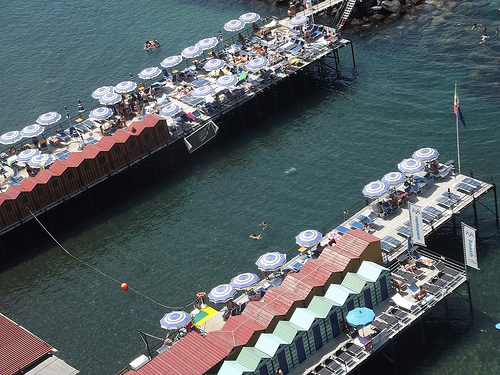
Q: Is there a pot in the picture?
A: No, there are no pots.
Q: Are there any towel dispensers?
A: No, there are no towel dispensers.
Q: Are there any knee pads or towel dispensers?
A: No, there are no towel dispensers or knee pads.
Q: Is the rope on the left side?
A: Yes, the rope is on the left of the image.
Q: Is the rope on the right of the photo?
A: No, the rope is on the left of the image.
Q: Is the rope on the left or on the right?
A: The rope is on the left of the image.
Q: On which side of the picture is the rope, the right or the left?
A: The rope is on the left of the image.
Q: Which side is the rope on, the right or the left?
A: The rope is on the left of the image.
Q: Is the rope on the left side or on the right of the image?
A: The rope is on the left of the image.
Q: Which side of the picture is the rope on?
A: The rope is on the left of the image.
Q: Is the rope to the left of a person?
A: Yes, the rope is to the left of a person.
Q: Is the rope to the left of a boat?
A: No, the rope is to the left of a person.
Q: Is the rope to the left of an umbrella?
A: Yes, the rope is to the left of an umbrella.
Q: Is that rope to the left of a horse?
A: No, the rope is to the left of an umbrella.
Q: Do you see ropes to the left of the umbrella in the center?
A: Yes, there is a rope to the left of the umbrella.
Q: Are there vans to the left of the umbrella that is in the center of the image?
A: No, there is a rope to the left of the umbrella.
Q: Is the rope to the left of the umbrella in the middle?
A: Yes, the rope is to the left of the umbrella.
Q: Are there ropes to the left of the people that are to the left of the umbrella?
A: Yes, there is a rope to the left of the people.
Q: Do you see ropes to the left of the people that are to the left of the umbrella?
A: Yes, there is a rope to the left of the people.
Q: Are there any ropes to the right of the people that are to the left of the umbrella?
A: No, the rope is to the left of the people.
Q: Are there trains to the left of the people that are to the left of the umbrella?
A: No, there is a rope to the left of the people.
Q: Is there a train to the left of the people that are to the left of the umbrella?
A: No, there is a rope to the left of the people.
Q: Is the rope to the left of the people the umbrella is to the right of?
A: Yes, the rope is to the left of the people.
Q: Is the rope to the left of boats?
A: No, the rope is to the left of the people.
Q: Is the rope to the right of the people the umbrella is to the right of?
A: No, the rope is to the left of the people.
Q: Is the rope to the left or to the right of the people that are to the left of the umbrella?
A: The rope is to the left of the people.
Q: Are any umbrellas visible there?
A: Yes, there is an umbrella.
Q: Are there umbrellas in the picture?
A: Yes, there is an umbrella.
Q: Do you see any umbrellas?
A: Yes, there is an umbrella.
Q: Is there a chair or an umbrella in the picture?
A: Yes, there is an umbrella.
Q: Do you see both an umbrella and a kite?
A: No, there is an umbrella but no kites.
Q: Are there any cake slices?
A: No, there are no cake slices.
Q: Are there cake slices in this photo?
A: No, there are no cake slices.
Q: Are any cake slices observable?
A: No, there are no cake slices.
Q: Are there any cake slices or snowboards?
A: No, there are no cake slices or snowboards.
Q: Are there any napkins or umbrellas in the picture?
A: Yes, there is an umbrella.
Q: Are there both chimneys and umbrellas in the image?
A: No, there is an umbrella but no chimneys.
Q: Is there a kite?
A: No, there are no kites.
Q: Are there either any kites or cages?
A: No, there are no kites or cages.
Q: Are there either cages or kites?
A: No, there are no kites or cages.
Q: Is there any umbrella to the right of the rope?
A: Yes, there is an umbrella to the right of the rope.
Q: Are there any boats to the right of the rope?
A: No, there is an umbrella to the right of the rope.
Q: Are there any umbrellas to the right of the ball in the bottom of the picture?
A: Yes, there is an umbrella to the right of the ball.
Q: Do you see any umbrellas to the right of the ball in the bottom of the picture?
A: Yes, there is an umbrella to the right of the ball.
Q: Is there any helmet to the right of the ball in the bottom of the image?
A: No, there is an umbrella to the right of the ball.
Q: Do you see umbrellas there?
A: Yes, there is an umbrella.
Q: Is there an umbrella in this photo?
A: Yes, there is an umbrella.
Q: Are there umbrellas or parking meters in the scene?
A: Yes, there is an umbrella.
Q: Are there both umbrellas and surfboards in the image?
A: No, there is an umbrella but no surfboards.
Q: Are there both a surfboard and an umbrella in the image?
A: No, there is an umbrella but no surfboards.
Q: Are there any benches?
A: No, there are no benches.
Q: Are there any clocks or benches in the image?
A: No, there are no benches or clocks.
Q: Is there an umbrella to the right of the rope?
A: Yes, there is an umbrella to the right of the rope.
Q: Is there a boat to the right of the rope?
A: No, there is an umbrella to the right of the rope.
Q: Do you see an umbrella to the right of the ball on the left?
A: Yes, there is an umbrella to the right of the ball.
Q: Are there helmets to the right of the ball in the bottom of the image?
A: No, there is an umbrella to the right of the ball.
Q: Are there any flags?
A: Yes, there is a flag.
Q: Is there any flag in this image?
A: Yes, there is a flag.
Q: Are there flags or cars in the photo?
A: Yes, there is a flag.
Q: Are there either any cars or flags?
A: Yes, there is a flag.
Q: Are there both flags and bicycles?
A: No, there is a flag but no bicycles.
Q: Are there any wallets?
A: No, there are no wallets.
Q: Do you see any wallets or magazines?
A: No, there are no wallets or magazines.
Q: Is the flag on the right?
A: Yes, the flag is on the right of the image.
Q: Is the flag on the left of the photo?
A: No, the flag is on the right of the image.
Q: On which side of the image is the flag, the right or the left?
A: The flag is on the right of the image.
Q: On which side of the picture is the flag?
A: The flag is on the right of the image.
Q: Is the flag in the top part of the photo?
A: Yes, the flag is in the top of the image.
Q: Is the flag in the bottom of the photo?
A: No, the flag is in the top of the image.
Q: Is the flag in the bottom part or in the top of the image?
A: The flag is in the top of the image.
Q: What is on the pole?
A: The flag is on the pole.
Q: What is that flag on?
A: The flag is on the pole.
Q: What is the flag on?
A: The flag is on the pole.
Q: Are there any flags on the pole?
A: Yes, there is a flag on the pole.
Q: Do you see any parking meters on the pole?
A: No, there is a flag on the pole.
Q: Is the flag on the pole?
A: Yes, the flag is on the pole.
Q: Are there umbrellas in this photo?
A: Yes, there is an umbrella.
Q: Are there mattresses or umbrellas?
A: Yes, there is an umbrella.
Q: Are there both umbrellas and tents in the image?
A: No, there is an umbrella but no tents.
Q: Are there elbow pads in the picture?
A: No, there are no elbow pads.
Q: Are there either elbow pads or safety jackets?
A: No, there are no elbow pads or safety jackets.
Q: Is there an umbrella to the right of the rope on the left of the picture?
A: Yes, there is an umbrella to the right of the rope.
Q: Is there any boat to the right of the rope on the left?
A: No, there is an umbrella to the right of the rope.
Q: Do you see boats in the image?
A: No, there are no boats.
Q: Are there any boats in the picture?
A: No, there are no boats.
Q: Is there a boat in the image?
A: No, there are no boats.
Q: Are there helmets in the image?
A: No, there are no helmets.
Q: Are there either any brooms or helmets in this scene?
A: No, there are no helmets or brooms.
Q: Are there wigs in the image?
A: No, there are no wigs.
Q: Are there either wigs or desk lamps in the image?
A: No, there are no wigs or desk lamps.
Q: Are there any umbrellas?
A: Yes, there is an umbrella.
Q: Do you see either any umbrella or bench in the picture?
A: Yes, there is an umbrella.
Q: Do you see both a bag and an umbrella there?
A: No, there is an umbrella but no bags.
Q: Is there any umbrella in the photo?
A: Yes, there is an umbrella.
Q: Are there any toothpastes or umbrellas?
A: Yes, there is an umbrella.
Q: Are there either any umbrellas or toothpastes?
A: Yes, there is an umbrella.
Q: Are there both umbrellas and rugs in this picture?
A: No, there is an umbrella but no rugs.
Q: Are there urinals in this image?
A: No, there are no urinals.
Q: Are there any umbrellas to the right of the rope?
A: Yes, there is an umbrella to the right of the rope.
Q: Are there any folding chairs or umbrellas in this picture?
A: Yes, there is an umbrella.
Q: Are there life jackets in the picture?
A: No, there are no life jackets.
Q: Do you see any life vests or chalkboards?
A: No, there are no life vests or chalkboards.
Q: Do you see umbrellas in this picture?
A: Yes, there is an umbrella.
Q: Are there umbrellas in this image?
A: Yes, there is an umbrella.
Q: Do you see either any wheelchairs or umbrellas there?
A: Yes, there is an umbrella.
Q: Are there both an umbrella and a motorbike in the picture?
A: No, there is an umbrella but no motorcycles.